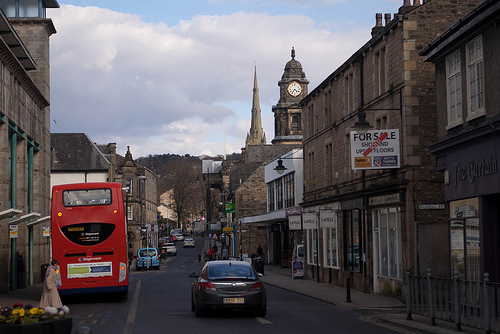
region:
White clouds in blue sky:
[61, 0, 273, 134]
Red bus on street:
[46, 177, 138, 304]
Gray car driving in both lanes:
[185, 257, 269, 318]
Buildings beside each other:
[266, 2, 498, 303]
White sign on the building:
[343, 113, 406, 177]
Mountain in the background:
[143, 146, 245, 242]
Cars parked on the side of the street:
[135, 218, 188, 271]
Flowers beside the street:
[1, 300, 74, 332]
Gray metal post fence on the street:
[394, 263, 499, 333]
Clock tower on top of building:
[270, 40, 312, 114]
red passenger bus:
[47, 180, 139, 303]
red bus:
[45, 176, 134, 292]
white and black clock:
[278, 73, 314, 109]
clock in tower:
[286, 81, 313, 97]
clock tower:
[280, 54, 300, 148]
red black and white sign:
[343, 126, 397, 170]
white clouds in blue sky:
[91, 31, 129, 80]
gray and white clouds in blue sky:
[120, 23, 202, 89]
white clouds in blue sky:
[117, 80, 157, 126]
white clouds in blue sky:
[182, 4, 243, 42]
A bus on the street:
[48, 186, 125, 294]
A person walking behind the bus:
[41, 259, 63, 306]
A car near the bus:
[193, 263, 268, 310]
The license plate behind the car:
[222, 296, 244, 303]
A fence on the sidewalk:
[407, 271, 499, 326]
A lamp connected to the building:
[273, 155, 305, 175]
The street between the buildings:
[77, 233, 394, 333]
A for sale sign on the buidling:
[347, 130, 399, 167]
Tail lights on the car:
[203, 280, 264, 291]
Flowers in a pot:
[0, 306, 68, 321]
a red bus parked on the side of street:
[52, 174, 132, 296]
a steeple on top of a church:
[242, 46, 264, 146]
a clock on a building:
[283, 71, 308, 96]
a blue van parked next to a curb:
[136, 245, 164, 275]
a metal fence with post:
[396, 272, 481, 314]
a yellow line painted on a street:
[113, 269, 143, 332]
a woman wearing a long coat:
[43, 259, 60, 318]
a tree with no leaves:
[161, 156, 198, 233]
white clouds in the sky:
[153, 69, 232, 149]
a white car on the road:
[181, 232, 193, 253]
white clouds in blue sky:
[71, 5, 99, 75]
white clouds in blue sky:
[80, 62, 141, 124]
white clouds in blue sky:
[139, 15, 173, 52]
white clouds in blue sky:
[184, 76, 222, 130]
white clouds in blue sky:
[93, 48, 158, 96]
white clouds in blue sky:
[170, 12, 217, 60]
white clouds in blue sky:
[305, 10, 340, 45]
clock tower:
[283, 47, 304, 107]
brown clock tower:
[284, 34, 309, 115]